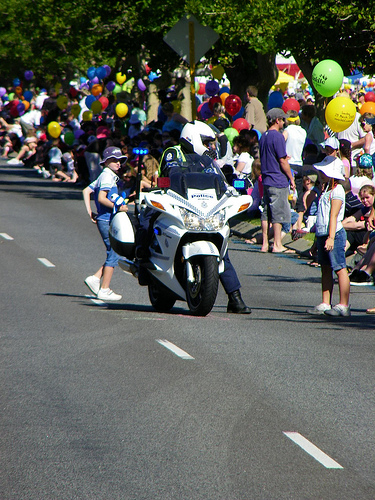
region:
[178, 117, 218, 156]
A white helmet on a motorcycle rider's head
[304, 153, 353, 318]
A small child standing in the street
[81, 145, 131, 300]
A child wearing a dark hat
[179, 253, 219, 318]
The front tire on the motorcycle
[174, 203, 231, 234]
The headlights on a motorcycle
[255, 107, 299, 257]
A man wearing a purple shirt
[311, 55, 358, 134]
Green and yellow balloons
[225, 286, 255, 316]
The motorcyclist's black boot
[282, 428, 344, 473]
A white line painted on the road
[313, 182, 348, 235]
A white shirt on the child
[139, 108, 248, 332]
a man sitting on a motorcycle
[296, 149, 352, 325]
a young child standing at the edge of the road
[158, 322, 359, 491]
white lines painted on a street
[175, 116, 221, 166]
a man wearing a motorcycle helmet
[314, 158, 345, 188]
a young child wearing a hat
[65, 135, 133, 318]
a young girl crossing a street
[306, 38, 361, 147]
a green and a yellow balloon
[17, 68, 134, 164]
several people holding balloons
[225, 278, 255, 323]
a man wearing black boots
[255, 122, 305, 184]
a man wearing a purple shirt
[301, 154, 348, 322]
a young girl standing in on a street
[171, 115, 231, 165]
a man wearing a white helmet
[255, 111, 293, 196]
a young man wearing a purple shirt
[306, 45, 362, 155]
a green and yellow balloon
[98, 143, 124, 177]
a young girl wearing a hat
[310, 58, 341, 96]
A large green balloon above a close girl.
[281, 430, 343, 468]
The biggest white road line.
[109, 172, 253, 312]
A white and black police motorcycle.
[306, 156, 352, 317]
A little girl standing in the road with a white hat on.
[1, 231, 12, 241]
The furthest white line in the road.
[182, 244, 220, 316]
Front black wheel on the police bike.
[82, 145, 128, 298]
Little girl in white shoes and a blue and white shirt walking behind a police bike.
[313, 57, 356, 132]
A green and yellow balloon above a girl.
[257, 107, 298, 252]
A man in black shorts and flip flops standing in the road.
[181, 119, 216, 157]
White helmet on a police officer on a bike.